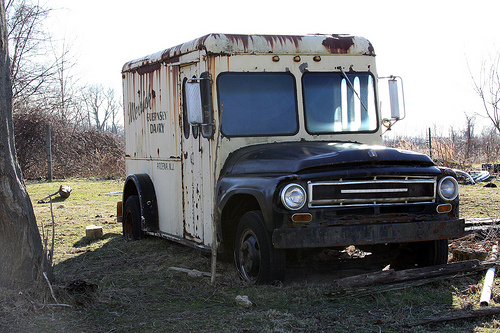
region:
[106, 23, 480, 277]
old truck on the grass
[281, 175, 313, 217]
headlight on the truck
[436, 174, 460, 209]
headlight on the truck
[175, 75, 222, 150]
side mirror on the truck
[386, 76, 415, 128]
side mirror on the truck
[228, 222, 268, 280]
wheel on the truck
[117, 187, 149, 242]
wheel on the truck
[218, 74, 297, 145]
windshield on the truck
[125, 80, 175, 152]
writing on the side of the truck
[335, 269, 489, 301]
log in font of the truck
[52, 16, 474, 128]
the sky is clear and bright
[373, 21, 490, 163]
the sky is clear and bright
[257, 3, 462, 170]
the sky is clear and bright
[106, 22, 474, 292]
Worn out milk truck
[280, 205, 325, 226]
Front turn signal on a vehicle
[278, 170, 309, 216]
Headlight on a vehicle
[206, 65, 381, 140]
Windshield on a vehicle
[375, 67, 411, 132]
Rearview mirror on a vehicle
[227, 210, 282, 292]
Front wheel and tire on a vehicle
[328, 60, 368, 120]
Windshield wiper on a vehicle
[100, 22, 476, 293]
Old truck rusting in the elements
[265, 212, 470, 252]
Front bumper on a vehicle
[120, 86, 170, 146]
Lettering on the side of a truck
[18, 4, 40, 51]
bare limbs on trees.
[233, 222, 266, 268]
rubber tire of vehicle.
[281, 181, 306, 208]
headlight on the vehicle.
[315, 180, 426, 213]
front grill of the vehicle.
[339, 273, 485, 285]
log near the vehicle.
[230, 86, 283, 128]
windshield of the vehicle.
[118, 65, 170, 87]
rust on the vehicle.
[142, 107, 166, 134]
writing on the side of the vehicle.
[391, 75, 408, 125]
mirror on side of vehicle.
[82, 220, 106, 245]
item on the grass.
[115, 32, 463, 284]
a white rusted dairy truck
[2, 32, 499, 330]
an old truck in a junk yard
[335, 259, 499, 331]
wood on the ground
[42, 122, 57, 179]
a metal pole in the back of the junk yard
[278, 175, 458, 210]
two headlights on the old truck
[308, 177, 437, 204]
the front grill of the truck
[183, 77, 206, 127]
the right side view mirror on the truck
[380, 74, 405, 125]
the left side view mirror on an old truck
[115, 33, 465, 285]
an old junk diary truck